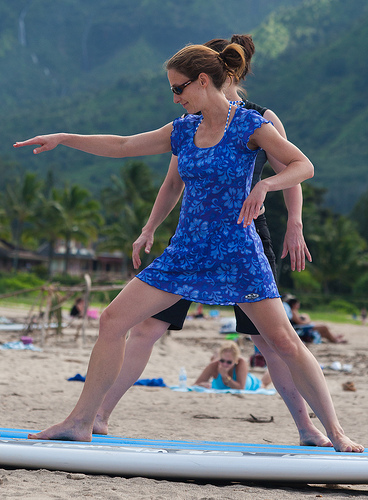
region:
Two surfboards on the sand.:
[0, 422, 364, 485]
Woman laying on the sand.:
[193, 342, 271, 398]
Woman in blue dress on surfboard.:
[13, 44, 356, 454]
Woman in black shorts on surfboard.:
[93, 20, 337, 447]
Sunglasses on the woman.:
[165, 79, 203, 95]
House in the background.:
[3, 217, 144, 282]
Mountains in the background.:
[2, 1, 360, 222]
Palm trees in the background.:
[2, 159, 366, 314]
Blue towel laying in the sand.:
[64, 368, 173, 396]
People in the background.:
[65, 290, 359, 355]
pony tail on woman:
[212, 46, 253, 80]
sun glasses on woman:
[164, 80, 200, 94]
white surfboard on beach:
[7, 452, 366, 484]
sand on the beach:
[141, 390, 196, 406]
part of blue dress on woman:
[192, 222, 245, 280]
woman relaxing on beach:
[193, 343, 260, 390]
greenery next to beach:
[315, 266, 364, 303]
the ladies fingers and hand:
[14, 133, 70, 163]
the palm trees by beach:
[25, 182, 94, 246]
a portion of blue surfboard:
[118, 434, 273, 449]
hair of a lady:
[164, 27, 202, 58]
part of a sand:
[158, 485, 176, 492]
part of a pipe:
[201, 463, 235, 491]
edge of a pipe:
[170, 459, 204, 472]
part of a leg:
[302, 382, 333, 405]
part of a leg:
[126, 362, 147, 387]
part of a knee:
[278, 343, 297, 358]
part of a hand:
[199, 362, 223, 387]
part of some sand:
[153, 395, 187, 423]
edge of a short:
[163, 311, 193, 344]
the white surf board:
[2, 436, 360, 493]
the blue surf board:
[127, 437, 366, 454]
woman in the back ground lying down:
[192, 343, 259, 398]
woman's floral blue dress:
[132, 111, 282, 292]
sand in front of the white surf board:
[17, 469, 116, 497]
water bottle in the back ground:
[176, 364, 190, 390]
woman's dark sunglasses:
[165, 77, 197, 94]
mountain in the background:
[26, 18, 151, 107]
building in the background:
[1, 226, 129, 284]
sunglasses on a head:
[157, 70, 206, 101]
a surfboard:
[11, 416, 364, 488]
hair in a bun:
[173, 35, 254, 91]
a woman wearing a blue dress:
[104, 61, 301, 310]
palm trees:
[23, 168, 99, 260]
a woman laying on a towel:
[181, 333, 267, 395]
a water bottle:
[160, 356, 200, 403]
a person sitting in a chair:
[282, 293, 347, 352]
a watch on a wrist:
[215, 372, 234, 387]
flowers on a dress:
[196, 221, 252, 257]